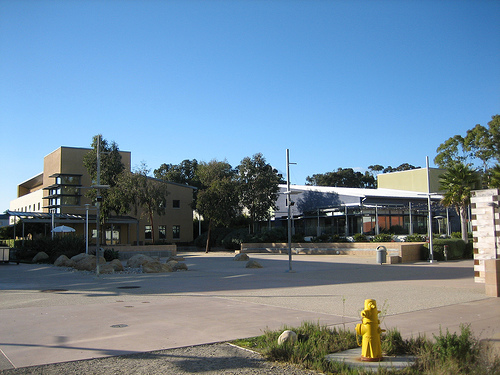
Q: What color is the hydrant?
A: Yellow.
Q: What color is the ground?
A: Tan.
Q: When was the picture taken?
A: Evening.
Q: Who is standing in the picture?
A: Nobody.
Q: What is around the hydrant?
A: Grass.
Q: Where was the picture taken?
A: School.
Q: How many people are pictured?
A: 0.